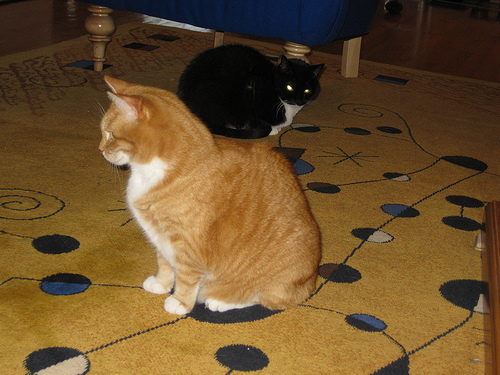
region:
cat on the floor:
[37, 101, 322, 321]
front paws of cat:
[122, 250, 204, 327]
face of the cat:
[85, 115, 130, 170]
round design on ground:
[27, 245, 107, 315]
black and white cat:
[170, 40, 340, 146]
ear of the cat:
[305, 52, 330, 82]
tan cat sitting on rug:
[88, 68, 329, 325]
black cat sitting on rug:
[173, 35, 330, 145]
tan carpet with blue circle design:
[1, 15, 499, 373]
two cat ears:
[95, 68, 155, 123]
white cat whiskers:
[81, 90, 133, 193]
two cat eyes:
[281, 78, 313, 97]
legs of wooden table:
[79, 0, 368, 90]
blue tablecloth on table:
[88, 0, 381, 52]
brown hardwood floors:
[311, 0, 499, 84]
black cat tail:
[202, 109, 277, 144]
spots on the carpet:
[317, 143, 463, 350]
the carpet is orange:
[5, 124, 125, 341]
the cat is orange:
[102, 92, 326, 322]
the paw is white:
[145, 281, 182, 321]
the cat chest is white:
[130, 169, 182, 260]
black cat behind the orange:
[137, 52, 347, 334]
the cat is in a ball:
[176, 45, 343, 145]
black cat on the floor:
[186, 39, 323, 140]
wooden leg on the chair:
[82, 11, 132, 73]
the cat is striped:
[167, 136, 325, 298]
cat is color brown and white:
[80, 56, 340, 324]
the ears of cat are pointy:
[97, 69, 159, 124]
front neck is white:
[118, 158, 175, 198]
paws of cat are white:
[132, 259, 200, 321]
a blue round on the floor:
[212, 336, 279, 373]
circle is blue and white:
[345, 219, 400, 250]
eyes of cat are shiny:
[171, 33, 328, 154]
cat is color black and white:
[170, 31, 331, 151]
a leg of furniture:
[74, 12, 125, 80]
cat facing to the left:
[84, 61, 344, 342]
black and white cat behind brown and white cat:
[93, 40, 325, 317]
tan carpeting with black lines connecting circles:
[7, 20, 483, 363]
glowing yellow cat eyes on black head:
[275, 57, 315, 102]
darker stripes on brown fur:
[135, 85, 315, 301]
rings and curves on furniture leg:
[82, 5, 112, 70]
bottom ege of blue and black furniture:
[140, 5, 390, 45]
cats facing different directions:
[95, 50, 322, 167]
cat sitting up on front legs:
[92, 72, 202, 317]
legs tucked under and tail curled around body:
[190, 35, 320, 135]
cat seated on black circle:
[92, 75, 322, 326]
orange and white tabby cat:
[93, 73, 321, 315]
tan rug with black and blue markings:
[1, 18, 499, 373]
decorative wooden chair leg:
[83, 2, 114, 71]